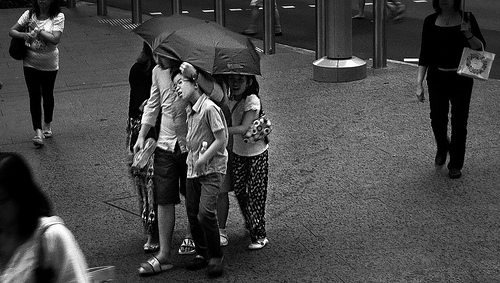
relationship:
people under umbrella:
[131, 46, 278, 276] [135, 14, 267, 83]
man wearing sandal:
[149, 50, 192, 279] [137, 250, 178, 281]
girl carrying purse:
[10, 0, 65, 145] [7, 28, 30, 61]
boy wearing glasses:
[171, 70, 239, 281] [169, 80, 190, 88]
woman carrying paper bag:
[412, 0, 499, 180] [456, 42, 498, 80]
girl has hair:
[10, 0, 65, 145] [26, 0, 71, 17]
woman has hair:
[412, 0, 499, 180] [424, 0, 476, 23]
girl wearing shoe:
[29, 0, 59, 149] [27, 124, 60, 153]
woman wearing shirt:
[412, 0, 499, 180] [415, 14, 487, 79]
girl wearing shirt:
[10, 0, 65, 145] [17, 15, 67, 79]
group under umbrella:
[131, 46, 278, 276] [135, 14, 267, 83]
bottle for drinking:
[127, 137, 168, 175] [128, 144, 151, 160]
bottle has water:
[130, 137, 157, 175] [137, 150, 154, 173]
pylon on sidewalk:
[301, 0, 373, 85] [4, 9, 493, 280]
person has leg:
[412, 0, 499, 180] [448, 85, 477, 179]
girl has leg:
[10, 0, 65, 145] [448, 85, 477, 179]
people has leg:
[226, 74, 272, 250] [448, 85, 477, 179]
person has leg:
[171, 70, 239, 281] [195, 175, 237, 272]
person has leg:
[149, 50, 192, 279] [151, 156, 185, 263]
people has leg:
[226, 74, 272, 250] [243, 153, 273, 250]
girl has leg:
[10, 0, 65, 145] [25, 75, 48, 144]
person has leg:
[119, 49, 163, 252] [122, 131, 163, 250]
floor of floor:
[7, 37, 398, 187] [7, 37, 398, 187]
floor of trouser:
[7, 37, 398, 187] [154, 165, 183, 202]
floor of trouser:
[7, 37, 398, 187] [41, 87, 62, 128]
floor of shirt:
[7, 37, 398, 187] [415, 14, 487, 79]